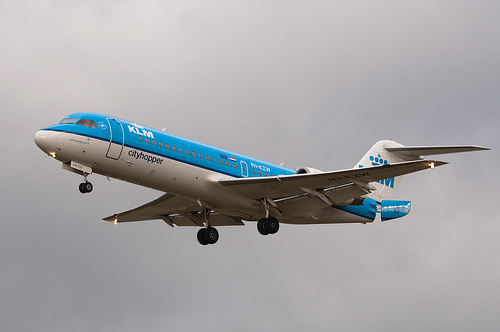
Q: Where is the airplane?
A: In the air.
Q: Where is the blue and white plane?
A: In the sky.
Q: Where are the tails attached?
A: Top and middle side of plane.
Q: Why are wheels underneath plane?
A: For landing.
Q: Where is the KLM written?
A: Front side of plane.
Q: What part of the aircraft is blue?
A: Top part.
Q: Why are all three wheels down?
A: Plane just taking off.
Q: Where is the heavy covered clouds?
A: Background of plane.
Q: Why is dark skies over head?
A: Late in afternoon.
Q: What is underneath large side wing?
A: Small light.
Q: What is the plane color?
A: Blue and white.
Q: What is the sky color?
A: Grey.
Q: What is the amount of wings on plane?
A: Two wings.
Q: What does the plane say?
A: KLM.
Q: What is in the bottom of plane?
A: Wheels.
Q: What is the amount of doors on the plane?
A: Two doors.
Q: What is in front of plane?
A: Windows.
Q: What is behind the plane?
A: Engine.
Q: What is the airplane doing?
A: Flying.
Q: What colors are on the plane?
A: Blue and white.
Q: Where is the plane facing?
A: Left.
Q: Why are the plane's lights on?
A: For visibility.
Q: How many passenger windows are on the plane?
A: 20.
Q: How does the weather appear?
A: Cloudy.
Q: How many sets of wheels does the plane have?
A: Three.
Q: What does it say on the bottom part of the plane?
A: Cityhopper.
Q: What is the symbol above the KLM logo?
A: A crown.